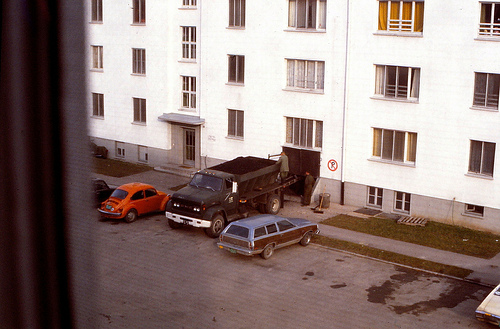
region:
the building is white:
[85, 0, 487, 210]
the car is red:
[99, 150, 166, 235]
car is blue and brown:
[206, 196, 318, 273]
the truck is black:
[143, 133, 250, 228]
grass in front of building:
[335, 196, 473, 265]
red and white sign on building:
[317, 147, 349, 177]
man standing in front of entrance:
[291, 152, 330, 209]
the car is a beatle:
[89, 156, 176, 230]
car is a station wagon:
[202, 184, 320, 271]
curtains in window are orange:
[380, 1, 421, 35]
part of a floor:
[191, 255, 222, 303]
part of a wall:
[348, 146, 378, 191]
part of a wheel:
[261, 238, 281, 258]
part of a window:
[389, 156, 409, 176]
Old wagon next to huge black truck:
[219, 211, 321, 260]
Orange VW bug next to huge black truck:
[98, 183, 168, 223]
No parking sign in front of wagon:
[327, 158, 337, 170]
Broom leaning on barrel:
[311, 181, 331, 211]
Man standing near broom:
[293, 165, 316, 206]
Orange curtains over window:
[380, 2, 422, 32]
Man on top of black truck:
[271, 149, 289, 180]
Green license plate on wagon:
[225, 244, 237, 255]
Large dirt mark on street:
[357, 262, 480, 315]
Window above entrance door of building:
[178, 73, 199, 110]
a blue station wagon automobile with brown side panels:
[214, 213, 320, 258]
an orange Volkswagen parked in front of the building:
[97, 180, 172, 224]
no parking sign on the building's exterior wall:
[326, 158, 338, 170]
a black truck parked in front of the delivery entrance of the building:
[165, 153, 297, 234]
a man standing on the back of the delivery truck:
[265, 147, 290, 178]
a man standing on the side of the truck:
[295, 165, 310, 205]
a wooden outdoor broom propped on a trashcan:
[310, 181, 326, 211]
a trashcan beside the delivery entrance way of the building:
[315, 190, 330, 206]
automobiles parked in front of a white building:
[90, 155, 317, 260]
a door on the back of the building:
[178, 125, 195, 167]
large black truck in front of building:
[168, 155, 295, 237]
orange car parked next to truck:
[96, 181, 169, 221]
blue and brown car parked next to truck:
[214, 213, 319, 260]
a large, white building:
[87, 0, 498, 234]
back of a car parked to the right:
[474, 278, 498, 323]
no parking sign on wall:
[328, 158, 338, 169]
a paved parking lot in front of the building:
[63, 198, 498, 326]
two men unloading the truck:
[274, 150, 314, 207]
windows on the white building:
[90, 3, 498, 215]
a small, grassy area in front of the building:
[90, 153, 498, 280]